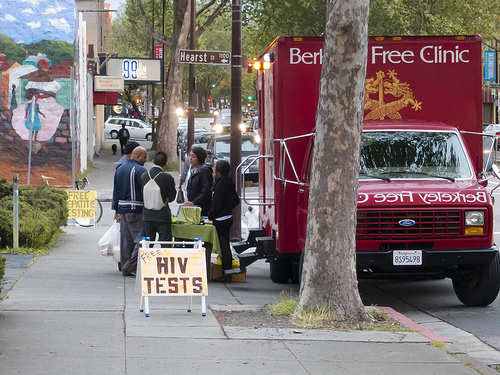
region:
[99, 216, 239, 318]
HIV TEST sign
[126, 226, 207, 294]
HIV TEST sign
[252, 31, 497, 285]
red box truck with Berkley Free Clinic on front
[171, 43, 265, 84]
brown and white street sign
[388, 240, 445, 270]
white icense tag with blue numbers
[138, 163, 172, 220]
white back pack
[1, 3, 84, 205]
picture painted on outside wall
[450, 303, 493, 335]
black asphalt street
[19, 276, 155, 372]
gray cement sidewalk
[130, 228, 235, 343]
sandwich board sign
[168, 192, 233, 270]
green table cloth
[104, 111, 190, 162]
white station wagon on side street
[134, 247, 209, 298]
sign set up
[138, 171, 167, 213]
backpack on man's back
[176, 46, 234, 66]
brown street sign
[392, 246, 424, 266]
license plate on truck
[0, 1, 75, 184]
mural painted on wall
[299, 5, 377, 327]
tree trunk growing on side of street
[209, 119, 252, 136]
headlights on oncoming car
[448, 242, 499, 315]
black tire on truck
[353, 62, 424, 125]
picture of two dragons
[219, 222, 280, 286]
steps to inside of truck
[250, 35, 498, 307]
Berkeley Free Clinic medical truck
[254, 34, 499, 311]
a red mobile medical truck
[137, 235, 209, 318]
a HIV Tests sign on the sidewalk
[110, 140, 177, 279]
three men inquiring about free HIV testing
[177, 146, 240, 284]
two Berkley Free Clinic employees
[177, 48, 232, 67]
a brown Hearst sign on a pole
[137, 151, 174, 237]
man in black sweater standing on the side of the table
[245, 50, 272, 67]
lights on the right side of the medical truck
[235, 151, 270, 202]
two hand support rails on the side of the medical truck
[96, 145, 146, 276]
man in blue sweater carrying white shopping bags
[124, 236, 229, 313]
a sign for free HIV tests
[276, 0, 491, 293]
a red vehicle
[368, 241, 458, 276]
California license plate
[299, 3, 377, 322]
a tree trunk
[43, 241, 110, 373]
the sidewalk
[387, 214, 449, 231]
a ford logo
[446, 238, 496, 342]
a tire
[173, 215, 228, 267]
a green table cloth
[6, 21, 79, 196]
a mural on the side of a building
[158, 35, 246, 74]
a sign for Hearst street